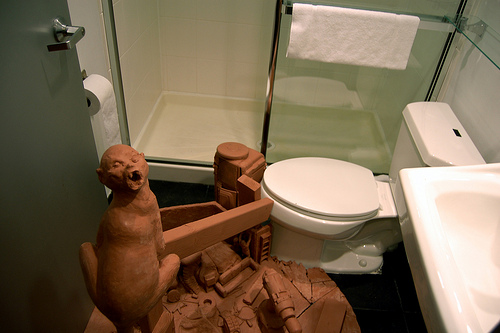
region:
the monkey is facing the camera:
[70, 118, 225, 326]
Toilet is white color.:
[281, 123, 448, 235]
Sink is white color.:
[412, 173, 498, 323]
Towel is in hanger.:
[293, 7, 420, 83]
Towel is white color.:
[293, 4, 417, 84]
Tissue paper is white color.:
[78, 73, 119, 116]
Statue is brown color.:
[86, 156, 311, 306]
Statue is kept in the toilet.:
[93, 160, 325, 327]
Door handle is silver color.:
[21, 5, 101, 80]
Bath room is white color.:
[151, 61, 367, 171]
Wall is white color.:
[449, 38, 497, 96]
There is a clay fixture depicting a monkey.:
[76, 141, 363, 329]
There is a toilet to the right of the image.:
[262, 100, 490, 272]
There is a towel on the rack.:
[286, 2, 419, 69]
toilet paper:
[80, 73, 125, 149]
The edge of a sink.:
[389, 160, 499, 330]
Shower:
[100, 0, 464, 182]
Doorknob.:
[45, 15, 87, 52]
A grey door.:
[0, 0, 112, 330]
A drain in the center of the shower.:
[255, 136, 275, 150]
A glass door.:
[257, 0, 469, 178]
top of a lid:
[301, 167, 337, 202]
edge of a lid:
[313, 207, 353, 224]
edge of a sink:
[408, 249, 445, 289]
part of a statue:
[186, 213, 248, 270]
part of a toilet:
[293, 136, 350, 251]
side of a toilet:
[295, 208, 349, 278]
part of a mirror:
[288, 84, 325, 145]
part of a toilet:
[286, 197, 333, 228]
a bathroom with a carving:
[2, 1, 495, 331]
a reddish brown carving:
[78, 138, 364, 329]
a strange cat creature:
[72, 140, 182, 330]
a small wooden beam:
[162, 195, 273, 258]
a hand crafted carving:
[162, 255, 360, 331]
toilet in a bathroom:
[260, 100, 485, 275]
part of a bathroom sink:
[391, 158, 496, 329]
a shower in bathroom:
[100, 0, 471, 187]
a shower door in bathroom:
[258, 0, 469, 176]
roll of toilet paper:
[81, 72, 122, 143]